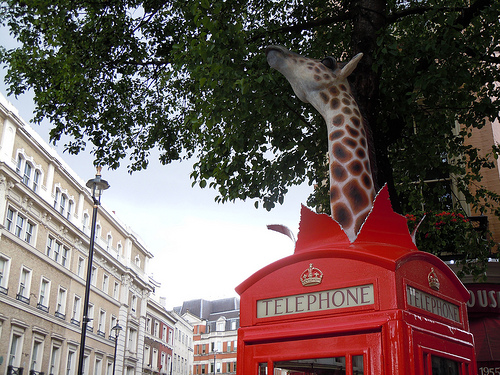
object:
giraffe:
[263, 42, 398, 245]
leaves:
[248, 51, 265, 82]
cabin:
[233, 180, 482, 374]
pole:
[76, 205, 99, 374]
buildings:
[192, 293, 239, 375]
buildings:
[170, 311, 194, 374]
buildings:
[141, 296, 179, 375]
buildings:
[0, 92, 157, 374]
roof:
[178, 298, 206, 320]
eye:
[318, 55, 339, 72]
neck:
[317, 93, 378, 242]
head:
[262, 42, 367, 104]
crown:
[297, 261, 324, 288]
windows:
[22, 159, 35, 189]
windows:
[58, 189, 68, 218]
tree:
[1, 1, 496, 282]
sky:
[90, 155, 267, 269]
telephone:
[261, 284, 371, 316]